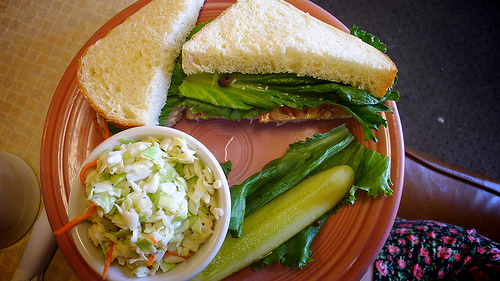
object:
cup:
[0, 151, 60, 253]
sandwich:
[74, 0, 205, 133]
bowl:
[66, 124, 230, 281]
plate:
[41, 0, 409, 281]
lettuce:
[220, 121, 397, 271]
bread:
[178, 0, 399, 99]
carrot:
[50, 159, 112, 240]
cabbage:
[113, 172, 180, 230]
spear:
[189, 164, 358, 280]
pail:
[251, 100, 328, 130]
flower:
[420, 237, 437, 258]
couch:
[436, 171, 475, 207]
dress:
[372, 217, 500, 281]